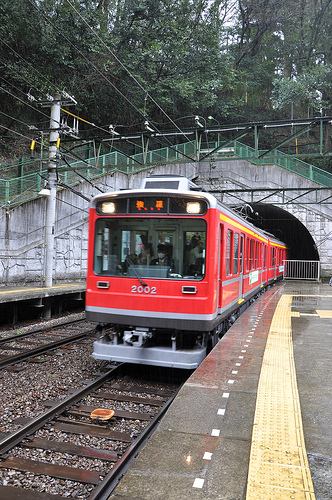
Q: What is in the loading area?
A: The train tracks.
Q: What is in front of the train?
A: The large window.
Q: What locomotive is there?
A: Train.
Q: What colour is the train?
A: Red.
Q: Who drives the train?
A: Conductor.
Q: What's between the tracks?
A: Gravel.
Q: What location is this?
A: Train station.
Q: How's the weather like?
A: Fair.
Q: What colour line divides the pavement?
A: Yellow.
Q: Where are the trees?
A: Background.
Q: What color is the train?
A: Red.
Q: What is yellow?
A: The line.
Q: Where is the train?
A: Outside a tunnel.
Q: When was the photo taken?
A: Daytime.